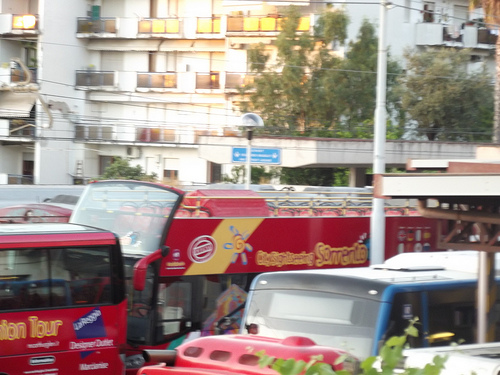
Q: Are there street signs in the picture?
A: Yes, there is a street sign.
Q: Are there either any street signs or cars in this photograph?
A: Yes, there is a street sign.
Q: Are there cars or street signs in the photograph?
A: Yes, there is a street sign.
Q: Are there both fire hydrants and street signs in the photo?
A: No, there is a street sign but no fire hydrants.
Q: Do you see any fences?
A: No, there are no fences.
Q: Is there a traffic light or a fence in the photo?
A: No, there are no fences or traffic lights.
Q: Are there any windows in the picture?
A: Yes, there is a window.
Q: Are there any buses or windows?
A: Yes, there is a window.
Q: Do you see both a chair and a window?
A: No, there is a window but no chairs.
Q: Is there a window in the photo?
A: Yes, there is a window.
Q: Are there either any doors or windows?
A: Yes, there is a window.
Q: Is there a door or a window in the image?
A: Yes, there is a window.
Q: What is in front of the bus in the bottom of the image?
A: The window is in front of the bus.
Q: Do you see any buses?
A: Yes, there is a bus.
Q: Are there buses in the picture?
A: Yes, there is a bus.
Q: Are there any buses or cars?
A: Yes, there is a bus.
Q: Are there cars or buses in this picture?
A: Yes, there is a bus.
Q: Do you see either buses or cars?
A: Yes, there is a bus.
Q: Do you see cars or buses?
A: Yes, there is a bus.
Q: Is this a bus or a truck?
A: This is a bus.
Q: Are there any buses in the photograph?
A: Yes, there is a bus.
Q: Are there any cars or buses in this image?
A: Yes, there is a bus.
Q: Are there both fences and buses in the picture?
A: No, there is a bus but no fences.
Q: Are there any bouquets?
A: No, there are no bouquets.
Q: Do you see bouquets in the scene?
A: No, there are no bouquets.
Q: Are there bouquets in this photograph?
A: No, there are no bouquets.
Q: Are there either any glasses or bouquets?
A: No, there are no bouquets or glasses.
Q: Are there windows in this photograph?
A: Yes, there is a window.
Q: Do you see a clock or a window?
A: Yes, there is a window.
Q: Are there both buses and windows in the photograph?
A: Yes, there are both a window and a bus.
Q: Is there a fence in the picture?
A: No, there are no fences.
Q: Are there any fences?
A: No, there are no fences.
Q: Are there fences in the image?
A: No, there are no fences.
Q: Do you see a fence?
A: No, there are no fences.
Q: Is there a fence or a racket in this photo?
A: No, there are no fences or rackets.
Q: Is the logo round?
A: Yes, the logo is round.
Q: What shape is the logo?
A: The logo is round.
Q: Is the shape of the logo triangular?
A: No, the logo is round.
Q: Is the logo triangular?
A: No, the logo is round.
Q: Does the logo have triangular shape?
A: No, the logo is round.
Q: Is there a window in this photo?
A: Yes, there is a window.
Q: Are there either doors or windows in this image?
A: Yes, there is a window.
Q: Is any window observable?
A: Yes, there is a window.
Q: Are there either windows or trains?
A: Yes, there is a window.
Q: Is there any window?
A: Yes, there is a window.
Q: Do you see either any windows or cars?
A: Yes, there is a window.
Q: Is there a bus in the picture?
A: Yes, there is a bus.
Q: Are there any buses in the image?
A: Yes, there is a bus.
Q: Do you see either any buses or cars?
A: Yes, there is a bus.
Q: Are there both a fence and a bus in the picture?
A: No, there is a bus but no fences.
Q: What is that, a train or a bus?
A: That is a bus.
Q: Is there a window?
A: Yes, there is a window.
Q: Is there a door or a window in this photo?
A: Yes, there is a window.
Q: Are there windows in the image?
A: Yes, there is a window.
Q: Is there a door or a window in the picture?
A: Yes, there is a window.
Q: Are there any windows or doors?
A: Yes, there is a window.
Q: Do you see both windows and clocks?
A: No, there is a window but no clocks.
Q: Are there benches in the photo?
A: No, there are no benches.